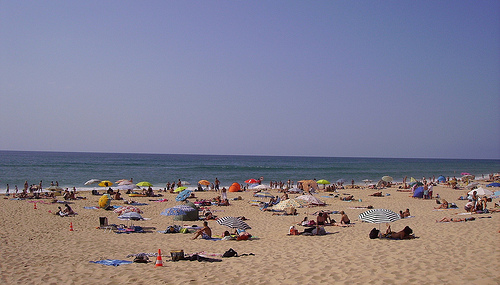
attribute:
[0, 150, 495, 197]
water — blue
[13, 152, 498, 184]
water — wavey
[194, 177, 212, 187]
umbrella — orange  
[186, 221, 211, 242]
person — laying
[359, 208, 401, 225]
umbrella — black, white, striped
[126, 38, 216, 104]
clouds — white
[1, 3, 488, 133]
sky — blue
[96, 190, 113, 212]
man sitting — is sitting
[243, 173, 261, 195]
umbrella — red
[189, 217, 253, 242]
people — sitting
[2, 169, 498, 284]
beach — busy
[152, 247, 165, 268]
striped con — orange and white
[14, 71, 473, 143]
clouds — white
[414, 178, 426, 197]
man — is sitting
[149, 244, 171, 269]
cone — white, orange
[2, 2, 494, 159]
sky — blue, clear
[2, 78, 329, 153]
clouds — white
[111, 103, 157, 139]
clouds — white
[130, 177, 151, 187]
umbrella — yellow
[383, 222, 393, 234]
man — is sitting